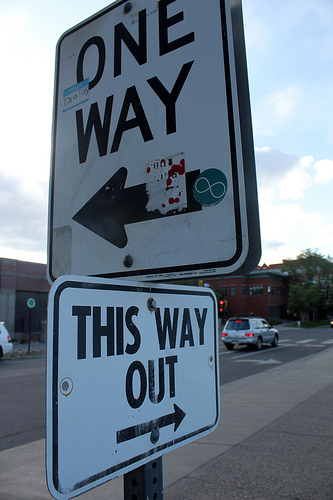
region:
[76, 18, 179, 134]
black letters on sign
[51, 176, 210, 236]
arrow pointing to the right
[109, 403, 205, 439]
arrow pointing to the left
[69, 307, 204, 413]
sign means exit here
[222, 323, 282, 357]
car stopped at light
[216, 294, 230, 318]
traffic signal is red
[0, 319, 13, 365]
white car is parked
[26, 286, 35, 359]
street light on side of road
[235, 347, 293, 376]
markings in the street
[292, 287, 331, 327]
trees near a building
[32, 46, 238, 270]
black and white sign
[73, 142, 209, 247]
arrow is pointing left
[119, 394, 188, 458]
arrow is pointing right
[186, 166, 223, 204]
green sticker on sign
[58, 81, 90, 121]
blue and white sticker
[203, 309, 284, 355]
grey van behind sign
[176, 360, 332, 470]
grey sidewalk behind sign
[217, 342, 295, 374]
white arrows on road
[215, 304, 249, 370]
red taillights on van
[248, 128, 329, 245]
white and puffy clouds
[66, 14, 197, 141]
black lettering on a white street sign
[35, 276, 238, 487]
white street sign on a grey metal pole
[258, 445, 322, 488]
grey stone surface of the sidewalk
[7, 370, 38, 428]
black asphalt surface of the road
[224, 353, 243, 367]
white lines painted on the road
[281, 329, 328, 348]
white stripes of the crosswalk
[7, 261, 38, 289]
brown stone wall of a building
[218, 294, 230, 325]
red stoplight on a black post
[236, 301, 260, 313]
red brick wall of a building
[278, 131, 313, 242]
blue cloudy skies over the street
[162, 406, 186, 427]
an arrow pointing a head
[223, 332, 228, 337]
break lights of a truck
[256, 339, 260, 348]
rare wheel of a truck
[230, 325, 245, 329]
rare window of a truck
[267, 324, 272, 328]
the side mirror of a truck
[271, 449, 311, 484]
the road pavement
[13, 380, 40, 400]
the tarmac road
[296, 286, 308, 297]
the green leaves of a tree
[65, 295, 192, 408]
a sign post showing this way out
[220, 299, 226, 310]
red lights in the background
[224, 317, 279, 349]
silver station wagon stopped at the light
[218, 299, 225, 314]
red traffic light at intersection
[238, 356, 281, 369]
right turn arrow painted on road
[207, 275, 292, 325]
red brick building across interesection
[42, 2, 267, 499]
two white signs on a black pole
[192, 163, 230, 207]
green infinity sticker on One Way sign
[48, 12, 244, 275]
black and white one way sign pointed left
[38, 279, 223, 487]
bottom sign pointing right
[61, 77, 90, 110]
blue and white sticker on top sign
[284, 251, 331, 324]
tree beside red brick building